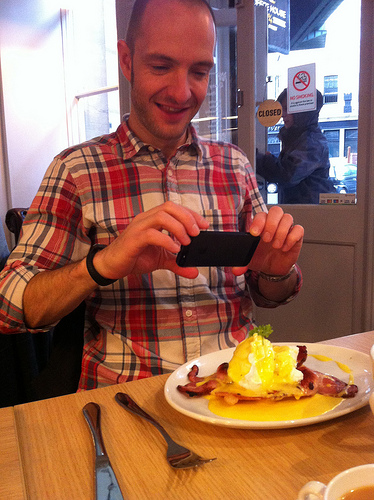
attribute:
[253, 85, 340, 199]
woman — entering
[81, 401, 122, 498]
utensil — eating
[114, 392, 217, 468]
utensil — eating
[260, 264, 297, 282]
watch — metal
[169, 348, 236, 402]
bacon — sliced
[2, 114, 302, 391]
shirt — plaid, blue, white, red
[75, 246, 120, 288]
wristwatch — black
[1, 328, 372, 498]
table top — wooden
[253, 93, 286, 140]
sign — "closed"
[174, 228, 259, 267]
smartphone — black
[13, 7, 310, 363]
man — smiling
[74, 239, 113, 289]
wristband — black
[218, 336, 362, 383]
eggs — poached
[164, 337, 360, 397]
bacon — sliced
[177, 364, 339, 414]
bacon — Slices 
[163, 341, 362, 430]
plate — delicious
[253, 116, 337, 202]
jacket — black